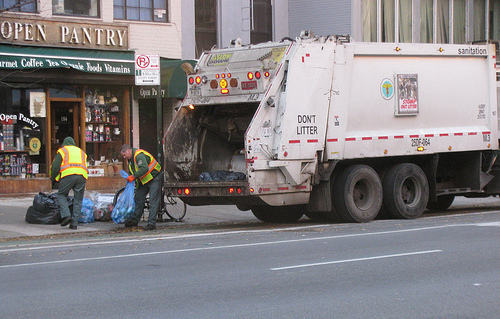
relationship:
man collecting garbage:
[119, 142, 164, 229] [20, 169, 140, 224]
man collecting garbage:
[48, 135, 88, 227] [20, 169, 140, 224]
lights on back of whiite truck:
[179, 69, 276, 89] [162, 28, 499, 224]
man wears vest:
[119, 144, 164, 229] [125, 148, 162, 183]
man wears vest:
[48, 136, 88, 231] [52, 144, 91, 183]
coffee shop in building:
[3, 7, 138, 222] [5, 6, 145, 208]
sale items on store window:
[3, 124, 30, 179] [83, 82, 123, 157]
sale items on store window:
[85, 89, 122, 144] [1, 80, 45, 174]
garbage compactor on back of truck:
[161, 40, 288, 202] [149, 27, 498, 228]